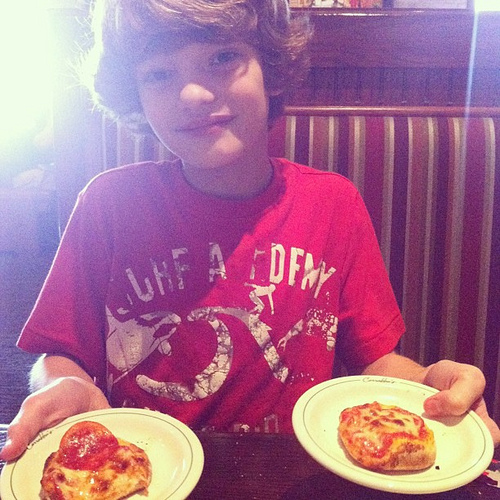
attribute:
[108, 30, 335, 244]
boy — sitting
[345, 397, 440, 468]
pizza — white, hot, small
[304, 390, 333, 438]
plate — white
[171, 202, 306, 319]
shirt — red